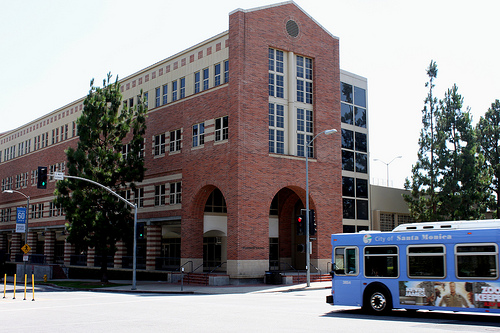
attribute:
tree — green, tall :
[405, 44, 480, 249]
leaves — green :
[50, 71, 147, 251]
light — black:
[30, 162, 50, 193]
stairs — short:
[183, 270, 208, 286]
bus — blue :
[331, 219, 499, 329]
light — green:
[36, 166, 48, 191]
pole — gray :
[302, 133, 317, 292]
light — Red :
[297, 217, 304, 223]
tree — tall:
[415, 80, 493, 219]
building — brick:
[112, 0, 312, 265]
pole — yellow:
[29, 269, 41, 294]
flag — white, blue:
[14, 205, 26, 235]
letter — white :
[416, 233, 457, 240]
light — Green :
[34, 163, 49, 194]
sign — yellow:
[21, 241, 31, 256]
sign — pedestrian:
[20, 241, 31, 254]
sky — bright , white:
[384, 37, 406, 110]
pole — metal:
[37, 162, 144, 291]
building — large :
[6, 4, 342, 274]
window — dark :
[353, 85, 367, 106]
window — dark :
[353, 106, 363, 126]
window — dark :
[355, 132, 369, 151]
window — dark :
[341, 152, 354, 172]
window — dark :
[356, 201, 367, 216]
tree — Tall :
[17, 82, 192, 272]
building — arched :
[242, 102, 322, 227]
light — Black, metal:
[31, 162, 52, 192]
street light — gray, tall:
[297, 121, 332, 291]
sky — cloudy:
[7, 3, 497, 185]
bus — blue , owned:
[328, 227, 499, 319]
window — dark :
[361, 244, 397, 275]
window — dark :
[407, 244, 445, 279]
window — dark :
[453, 242, 498, 280]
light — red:
[297, 215, 302, 225]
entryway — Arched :
[268, 183, 317, 285]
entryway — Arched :
[184, 179, 231, 282]